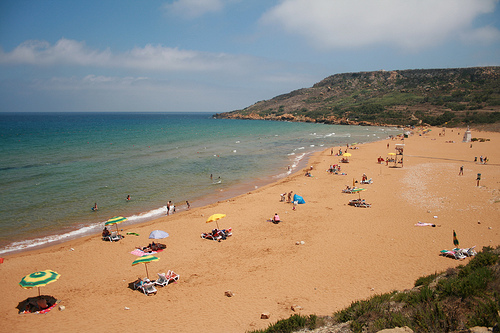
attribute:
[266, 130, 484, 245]
people — close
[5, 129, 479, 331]
beach — brown, close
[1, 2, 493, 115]
sky — close, blue, massive, big, clear, open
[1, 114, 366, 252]
water — blue, grey, white, close, calm, green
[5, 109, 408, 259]
water — blue